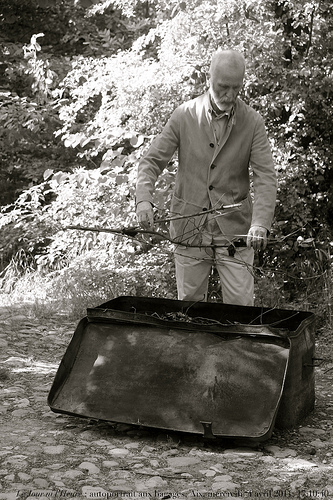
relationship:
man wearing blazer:
[135, 48, 277, 306] [135, 94, 278, 246]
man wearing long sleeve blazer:
[135, 48, 277, 306] [135, 94, 278, 246]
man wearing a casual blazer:
[135, 48, 277, 306] [135, 94, 278, 246]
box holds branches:
[47, 296, 314, 450] [69, 223, 245, 255]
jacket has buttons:
[135, 94, 278, 246] [209, 140, 217, 150]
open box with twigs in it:
[47, 296, 314, 450] [69, 223, 245, 255]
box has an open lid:
[47, 296, 314, 450] [50, 321, 290, 444]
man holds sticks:
[135, 48, 277, 306] [69, 223, 245, 255]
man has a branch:
[135, 48, 277, 306] [69, 223, 245, 255]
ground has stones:
[0, 1, 136, 268] [0, 215, 25, 269]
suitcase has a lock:
[47, 296, 314, 450] [201, 418, 214, 443]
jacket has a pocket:
[135, 94, 278, 246] [222, 200, 251, 229]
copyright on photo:
[15, 486, 332, 499] [0, 2, 332, 500]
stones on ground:
[0, 215, 25, 269] [2, 441, 333, 499]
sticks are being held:
[69, 223, 245, 255] [62, 217, 272, 258]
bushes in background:
[278, 2, 332, 235] [1, 0, 332, 49]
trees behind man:
[0, 1, 136, 268] [135, 48, 277, 306]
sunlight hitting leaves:
[1, 2, 205, 96] [14, 38, 130, 168]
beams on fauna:
[31, 65, 123, 247] [2, 10, 324, 296]